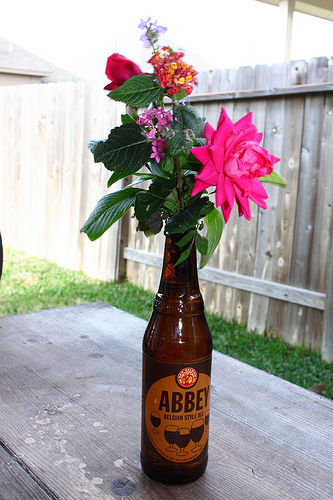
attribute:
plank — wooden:
[182, 59, 306, 105]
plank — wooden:
[24, 83, 54, 260]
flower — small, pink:
[152, 135, 169, 154]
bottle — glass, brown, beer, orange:
[141, 214, 210, 483]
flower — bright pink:
[187, 106, 285, 220]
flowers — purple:
[137, 14, 168, 49]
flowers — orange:
[146, 45, 200, 96]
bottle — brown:
[136, 217, 216, 490]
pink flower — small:
[141, 104, 175, 163]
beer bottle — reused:
[140, 219, 211, 487]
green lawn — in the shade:
[0, 248, 94, 316]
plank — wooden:
[247, 87, 309, 243]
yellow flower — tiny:
[170, 62, 177, 68]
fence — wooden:
[239, 235, 322, 301]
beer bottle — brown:
[133, 224, 217, 487]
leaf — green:
[108, 107, 187, 175]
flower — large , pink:
[179, 106, 292, 221]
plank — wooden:
[15, 78, 64, 250]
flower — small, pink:
[135, 105, 170, 155]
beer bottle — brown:
[124, 225, 236, 485]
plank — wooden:
[121, 246, 329, 310]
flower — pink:
[190, 107, 279, 223]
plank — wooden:
[259, 55, 312, 349]